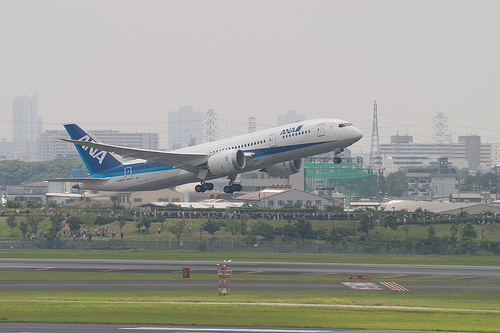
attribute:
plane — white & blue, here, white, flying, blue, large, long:
[77, 95, 362, 196]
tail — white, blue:
[56, 120, 127, 179]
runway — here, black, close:
[58, 251, 309, 300]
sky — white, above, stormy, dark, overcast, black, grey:
[142, 15, 238, 73]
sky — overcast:
[0, 0, 478, 120]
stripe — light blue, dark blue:
[99, 158, 329, 176]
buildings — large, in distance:
[2, 78, 483, 225]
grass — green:
[0, 287, 459, 331]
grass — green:
[1, 245, 484, 331]